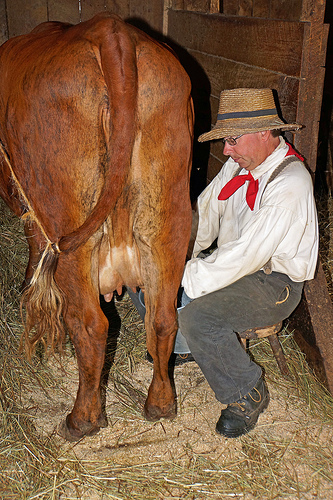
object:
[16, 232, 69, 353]
string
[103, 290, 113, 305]
teat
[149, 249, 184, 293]
surface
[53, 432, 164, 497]
straw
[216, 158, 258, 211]
handkerchief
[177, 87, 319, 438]
man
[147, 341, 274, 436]
boots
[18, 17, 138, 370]
rope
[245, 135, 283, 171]
neck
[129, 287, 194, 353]
bucket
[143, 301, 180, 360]
knees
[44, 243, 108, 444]
leg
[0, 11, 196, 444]
animal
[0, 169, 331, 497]
hay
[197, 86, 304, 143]
hat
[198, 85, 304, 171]
head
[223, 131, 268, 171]
face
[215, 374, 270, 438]
boot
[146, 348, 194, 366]
boot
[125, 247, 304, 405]
pants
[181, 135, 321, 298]
shirt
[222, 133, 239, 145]
glasses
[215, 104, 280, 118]
band